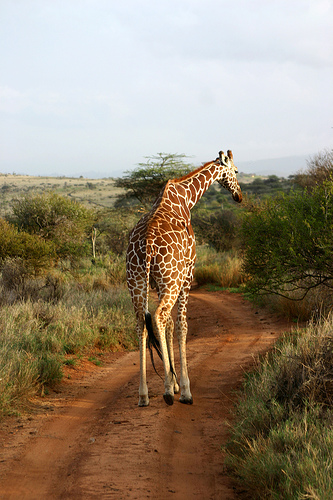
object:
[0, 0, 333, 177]
sky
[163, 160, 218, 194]
mane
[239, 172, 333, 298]
tree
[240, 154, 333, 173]
mountain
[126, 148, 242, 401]
giraffe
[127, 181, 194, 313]
coat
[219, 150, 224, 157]
horn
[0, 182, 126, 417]
grass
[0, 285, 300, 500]
dirt road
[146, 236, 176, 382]
tail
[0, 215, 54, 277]
tree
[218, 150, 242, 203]
head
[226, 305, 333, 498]
dry grass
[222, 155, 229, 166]
ear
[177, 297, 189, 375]
legs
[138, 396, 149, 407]
hooves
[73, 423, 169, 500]
dirt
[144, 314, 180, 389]
tip